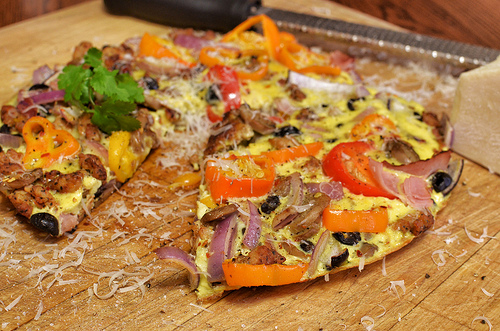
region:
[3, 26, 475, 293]
slices of pizza on the table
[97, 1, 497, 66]
a cheese grader in the background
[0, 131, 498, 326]
cheese shavings from the pizza are on the table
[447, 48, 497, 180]
a block of fresh cheese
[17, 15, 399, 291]
orange pepper slices on the pizza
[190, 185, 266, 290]
red onion slices on the pizza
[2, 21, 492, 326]
the table is of wood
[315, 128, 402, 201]
a slice of tomato in on the pizza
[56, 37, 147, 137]
a sprig of parsley is on the pizza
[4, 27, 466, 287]
black olives are sprinkled througout the pizza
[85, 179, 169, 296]
the cheese is grated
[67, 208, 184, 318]
the cheese is grated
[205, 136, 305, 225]
a slice of pepper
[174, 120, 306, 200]
a slice of pepper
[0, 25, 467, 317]
the pizza on the cutting board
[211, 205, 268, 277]
the onion slices on the pizza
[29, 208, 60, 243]
the olice on the pizza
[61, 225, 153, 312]
the grated cheese on the cutting board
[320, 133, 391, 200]
the tomato slice on the pizza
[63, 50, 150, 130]
the green parsley on the pizza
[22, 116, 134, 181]
the orange pepper on the pizza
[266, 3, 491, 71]
the grater on the cuttingboard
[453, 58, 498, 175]
the cheese block on the cutting board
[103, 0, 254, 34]
the black handle for the chees grater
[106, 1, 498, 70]
a knife on the board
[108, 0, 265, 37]
a black handle of the knife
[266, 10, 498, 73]
the blade of the knife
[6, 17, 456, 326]
a wooden cutting board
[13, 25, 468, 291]
a pizza on a board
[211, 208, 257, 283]
red onions on the pizza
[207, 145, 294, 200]
peppers on the pizza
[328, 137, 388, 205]
tomatoes on the pizza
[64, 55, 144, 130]
lettuce on the pizza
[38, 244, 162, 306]
cheese on the cutting board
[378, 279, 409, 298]
mozzerella cheese on board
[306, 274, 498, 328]
a wooden cutting board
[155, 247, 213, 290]
purple onion topping on pizza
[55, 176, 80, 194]
chicken topping on pizza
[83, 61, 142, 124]
green lettuce on pizza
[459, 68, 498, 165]
brown napkin on board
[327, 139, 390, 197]
red tomato topping on pizza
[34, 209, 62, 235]
black olive topping on pizza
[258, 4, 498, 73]
blade of knife in background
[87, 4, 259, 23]
black handle on the knife